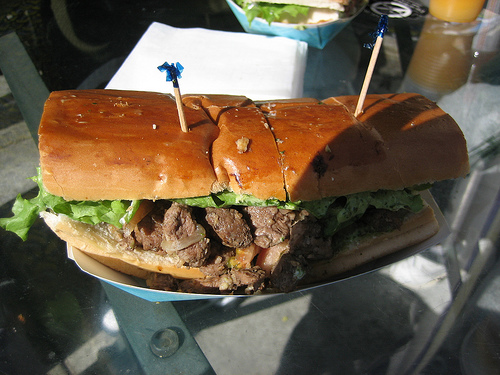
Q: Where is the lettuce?
A: On the sandwich.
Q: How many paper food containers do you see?
A: Two.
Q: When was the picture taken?
A: Daytime.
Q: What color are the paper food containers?
A: Blue.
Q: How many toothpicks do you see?
A: Two.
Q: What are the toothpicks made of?
A: Wood.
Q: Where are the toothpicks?
A: In the sandwich.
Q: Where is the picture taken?
A: At a table.